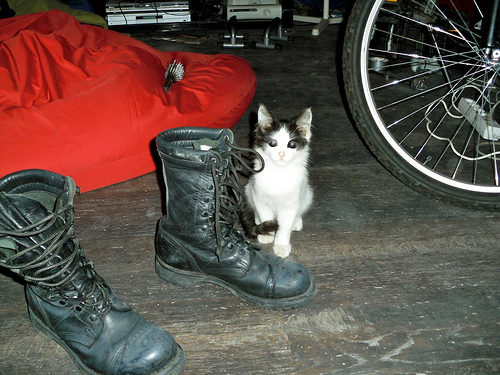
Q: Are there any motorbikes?
A: No, there are no motorbikes.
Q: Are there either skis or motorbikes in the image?
A: No, there are no motorbikes or skis.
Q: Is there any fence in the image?
A: No, there are no fences.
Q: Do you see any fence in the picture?
A: No, there are no fences.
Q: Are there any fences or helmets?
A: No, there are no fences or helmets.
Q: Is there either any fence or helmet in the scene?
A: No, there are no fences or helmets.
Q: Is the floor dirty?
A: Yes, the floor is dirty.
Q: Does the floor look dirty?
A: Yes, the floor is dirty.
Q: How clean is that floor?
A: The floor is dirty.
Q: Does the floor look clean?
A: No, the floor is dirty.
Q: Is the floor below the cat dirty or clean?
A: The floor is dirty.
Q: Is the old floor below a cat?
A: Yes, the floor is below a cat.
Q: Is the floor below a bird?
A: No, the floor is below a cat.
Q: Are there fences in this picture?
A: No, there are no fences.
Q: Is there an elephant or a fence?
A: No, there are no fences or elephants.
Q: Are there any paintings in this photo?
A: No, there are no paintings.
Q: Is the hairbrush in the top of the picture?
A: Yes, the hairbrush is in the top of the image.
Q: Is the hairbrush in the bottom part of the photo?
A: No, the hairbrush is in the top of the image.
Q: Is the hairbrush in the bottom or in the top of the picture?
A: The hairbrush is in the top of the image.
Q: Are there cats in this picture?
A: Yes, there is a cat.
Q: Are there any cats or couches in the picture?
A: Yes, there is a cat.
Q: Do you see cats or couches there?
A: Yes, there is a cat.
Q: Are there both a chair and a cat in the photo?
A: No, there is a cat but no chairs.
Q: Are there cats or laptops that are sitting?
A: Yes, the cat is sitting.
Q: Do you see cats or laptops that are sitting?
A: Yes, the cat is sitting.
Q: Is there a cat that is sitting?
A: Yes, there is a cat that is sitting.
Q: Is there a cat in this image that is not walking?
A: Yes, there is a cat that is sitting.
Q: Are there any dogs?
A: No, there are no dogs.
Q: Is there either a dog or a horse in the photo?
A: No, there are no dogs or horses.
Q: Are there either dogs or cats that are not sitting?
A: No, there is a cat but it is sitting.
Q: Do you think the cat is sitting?
A: Yes, the cat is sitting.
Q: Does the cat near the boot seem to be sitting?
A: Yes, the cat is sitting.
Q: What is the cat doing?
A: The cat is sitting.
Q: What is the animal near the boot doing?
A: The cat is sitting.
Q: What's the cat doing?
A: The cat is sitting.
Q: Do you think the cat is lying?
A: No, the cat is sitting.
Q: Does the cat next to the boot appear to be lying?
A: No, the cat is sitting.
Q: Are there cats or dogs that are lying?
A: No, there is a cat but it is sitting.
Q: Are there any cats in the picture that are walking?
A: No, there is a cat but it is sitting.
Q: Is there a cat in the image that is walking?
A: No, there is a cat but it is sitting.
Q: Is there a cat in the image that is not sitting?
A: No, there is a cat but it is sitting.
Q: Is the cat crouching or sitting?
A: The cat is sitting.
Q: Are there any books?
A: No, there are no books.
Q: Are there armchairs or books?
A: No, there are no books or armchairs.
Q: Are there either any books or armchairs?
A: No, there are no books or armchairs.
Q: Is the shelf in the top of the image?
A: Yes, the shelf is in the top of the image.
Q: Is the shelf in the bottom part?
A: No, the shelf is in the top of the image.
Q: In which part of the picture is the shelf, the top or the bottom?
A: The shelf is in the top of the image.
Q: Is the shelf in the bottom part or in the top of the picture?
A: The shelf is in the top of the image.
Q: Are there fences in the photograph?
A: No, there are no fences.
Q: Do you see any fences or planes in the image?
A: No, there are no fences or planes.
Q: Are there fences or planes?
A: No, there are no fences or planes.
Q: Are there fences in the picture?
A: No, there are no fences.